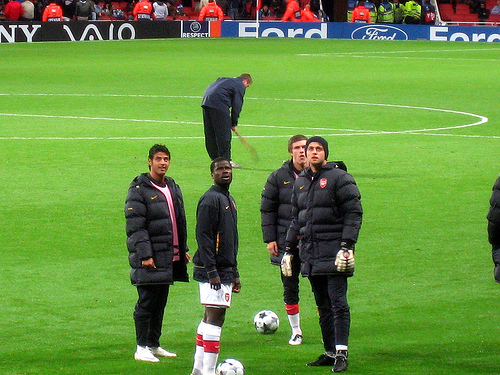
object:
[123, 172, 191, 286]
jacket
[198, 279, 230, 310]
shorts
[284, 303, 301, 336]
socks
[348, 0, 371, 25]
people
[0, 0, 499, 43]
stands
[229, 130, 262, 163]
bat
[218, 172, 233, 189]
goatee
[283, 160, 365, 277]
jacket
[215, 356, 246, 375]
soccer ball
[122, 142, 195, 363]
man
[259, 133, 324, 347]
man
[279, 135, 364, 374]
man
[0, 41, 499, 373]
soccer field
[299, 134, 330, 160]
hat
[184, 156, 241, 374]
man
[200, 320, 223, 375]
socks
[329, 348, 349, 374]
shoes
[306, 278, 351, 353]
pants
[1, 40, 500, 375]
grass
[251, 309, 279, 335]
soccer ball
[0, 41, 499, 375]
ground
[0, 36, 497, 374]
turf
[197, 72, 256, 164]
man